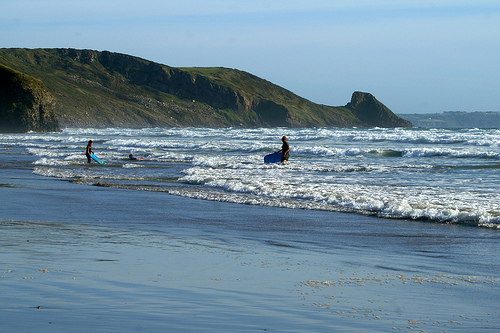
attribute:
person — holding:
[278, 135, 295, 168]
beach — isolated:
[2, 136, 498, 331]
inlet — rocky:
[3, 5, 495, 281]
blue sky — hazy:
[2, 2, 499, 112]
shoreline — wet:
[6, 179, 483, 327]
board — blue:
[262, 151, 288, 165]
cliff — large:
[7, 33, 408, 134]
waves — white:
[46, 127, 484, 207]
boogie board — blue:
[89, 150, 104, 165]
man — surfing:
[264, 124, 295, 171]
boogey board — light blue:
[85, 146, 112, 165]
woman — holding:
[275, 134, 303, 164]